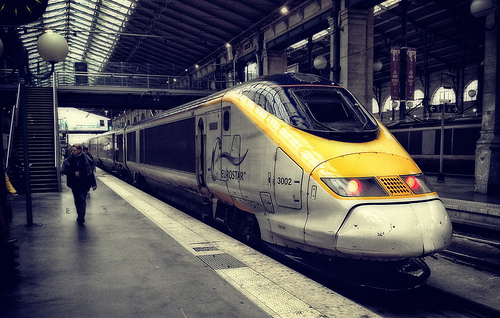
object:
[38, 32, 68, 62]
light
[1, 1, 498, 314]
station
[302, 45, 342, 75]
light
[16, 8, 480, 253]
station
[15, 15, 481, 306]
station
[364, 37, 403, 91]
light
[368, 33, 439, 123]
flag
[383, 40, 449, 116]
flag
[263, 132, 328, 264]
door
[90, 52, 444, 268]
train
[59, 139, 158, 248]
person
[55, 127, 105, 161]
head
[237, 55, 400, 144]
windshield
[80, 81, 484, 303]
train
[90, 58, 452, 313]
train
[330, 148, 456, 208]
headlight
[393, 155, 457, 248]
headlight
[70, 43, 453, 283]
train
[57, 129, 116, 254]
person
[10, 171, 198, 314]
platform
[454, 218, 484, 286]
tracks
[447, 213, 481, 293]
tracks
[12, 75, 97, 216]
stairway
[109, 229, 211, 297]
platform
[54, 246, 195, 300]
part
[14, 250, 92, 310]
platform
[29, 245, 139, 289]
part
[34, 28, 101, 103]
light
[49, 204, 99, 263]
platform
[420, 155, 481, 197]
platform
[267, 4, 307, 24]
light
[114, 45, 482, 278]
train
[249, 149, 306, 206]
number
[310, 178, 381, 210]
headlight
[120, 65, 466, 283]
train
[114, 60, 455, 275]
train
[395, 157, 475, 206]
headlight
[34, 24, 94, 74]
lamp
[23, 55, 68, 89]
pole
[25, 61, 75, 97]
pole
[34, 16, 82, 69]
lamp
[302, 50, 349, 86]
lamp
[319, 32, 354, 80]
pole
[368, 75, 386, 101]
pole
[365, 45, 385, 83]
lamp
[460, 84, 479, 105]
lamp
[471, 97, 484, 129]
pole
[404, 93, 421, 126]
pole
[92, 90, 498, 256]
train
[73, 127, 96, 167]
head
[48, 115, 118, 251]
person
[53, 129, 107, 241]
person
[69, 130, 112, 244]
person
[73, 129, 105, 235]
person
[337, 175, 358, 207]
headlight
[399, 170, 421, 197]
headlight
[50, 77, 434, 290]
train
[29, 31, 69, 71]
light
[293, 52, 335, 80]
light